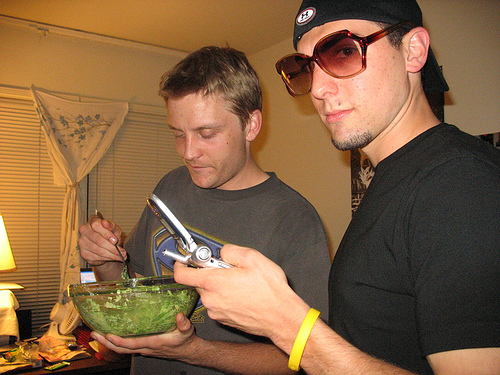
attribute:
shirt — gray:
[351, 190, 443, 277]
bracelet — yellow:
[262, 289, 335, 373]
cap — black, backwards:
[290, 6, 455, 73]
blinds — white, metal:
[3, 86, 194, 338]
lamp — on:
[0, 213, 20, 275]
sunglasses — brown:
[274, 18, 411, 97]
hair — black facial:
[316, 117, 371, 164]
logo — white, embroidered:
[279, 14, 336, 35]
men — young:
[178, 8, 495, 373]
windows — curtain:
[6, 83, 233, 337]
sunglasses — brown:
[273, 32, 411, 97]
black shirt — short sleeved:
[327, 124, 499, 364]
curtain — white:
[30, 85, 131, 332]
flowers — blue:
[31, 103, 113, 157]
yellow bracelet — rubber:
[288, 306, 324, 373]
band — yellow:
[266, 290, 361, 373]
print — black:
[298, 10, 309, 20]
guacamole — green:
[75, 275, 184, 344]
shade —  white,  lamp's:
[2, 213, 14, 274]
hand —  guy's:
[90, 304, 195, 358]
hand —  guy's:
[173, 242, 289, 342]